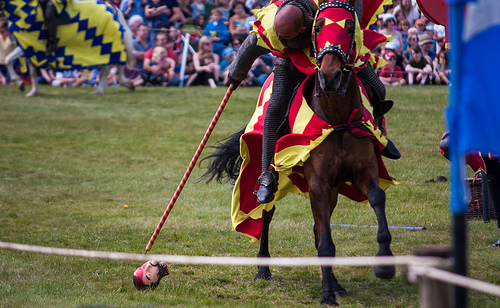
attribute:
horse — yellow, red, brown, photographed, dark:
[200, 1, 394, 307]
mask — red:
[310, 4, 357, 69]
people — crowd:
[0, 2, 451, 86]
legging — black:
[256, 55, 401, 204]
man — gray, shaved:
[228, 2, 402, 204]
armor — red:
[228, 1, 399, 203]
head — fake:
[133, 257, 170, 293]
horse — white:
[1, 1, 134, 98]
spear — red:
[146, 82, 234, 250]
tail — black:
[197, 127, 245, 184]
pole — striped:
[142, 81, 235, 253]